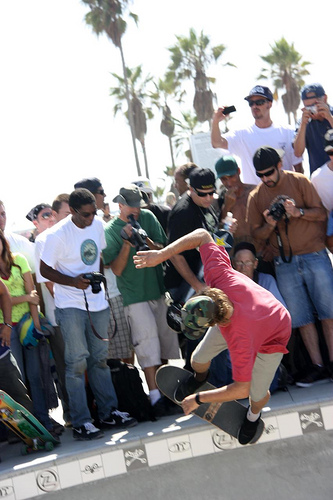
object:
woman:
[0, 234, 57, 441]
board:
[155, 363, 266, 446]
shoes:
[73, 420, 106, 441]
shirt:
[39, 217, 110, 311]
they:
[0, 82, 333, 453]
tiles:
[124, 442, 148, 471]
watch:
[194, 390, 203, 406]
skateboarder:
[131, 227, 292, 447]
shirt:
[198, 243, 293, 384]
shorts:
[191, 325, 283, 402]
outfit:
[199, 242, 292, 401]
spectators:
[38, 188, 134, 441]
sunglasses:
[194, 188, 217, 196]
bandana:
[25, 202, 53, 219]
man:
[101, 182, 171, 409]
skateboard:
[153, 362, 264, 446]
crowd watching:
[0, 83, 333, 289]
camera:
[267, 195, 288, 220]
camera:
[120, 213, 150, 252]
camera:
[83, 271, 104, 293]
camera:
[220, 104, 235, 114]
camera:
[303, 104, 318, 118]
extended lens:
[91, 280, 101, 294]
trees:
[83, 0, 141, 177]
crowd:
[0, 83, 332, 449]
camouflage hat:
[179, 295, 215, 341]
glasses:
[235, 260, 253, 266]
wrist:
[195, 389, 209, 405]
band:
[195, 392, 201, 406]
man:
[292, 80, 333, 172]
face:
[302, 97, 326, 119]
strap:
[82, 283, 118, 341]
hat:
[112, 184, 149, 209]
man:
[244, 147, 331, 372]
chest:
[262, 189, 303, 229]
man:
[233, 242, 285, 305]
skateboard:
[0, 389, 61, 455]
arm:
[159, 225, 228, 271]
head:
[191, 287, 230, 328]